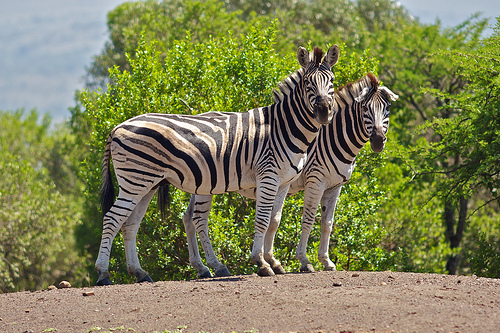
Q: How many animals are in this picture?
A: Two.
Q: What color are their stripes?
A: Black and White.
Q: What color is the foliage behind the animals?
A: Green.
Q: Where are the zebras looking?
A: Into the camera lense.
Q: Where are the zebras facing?
A: To the right.